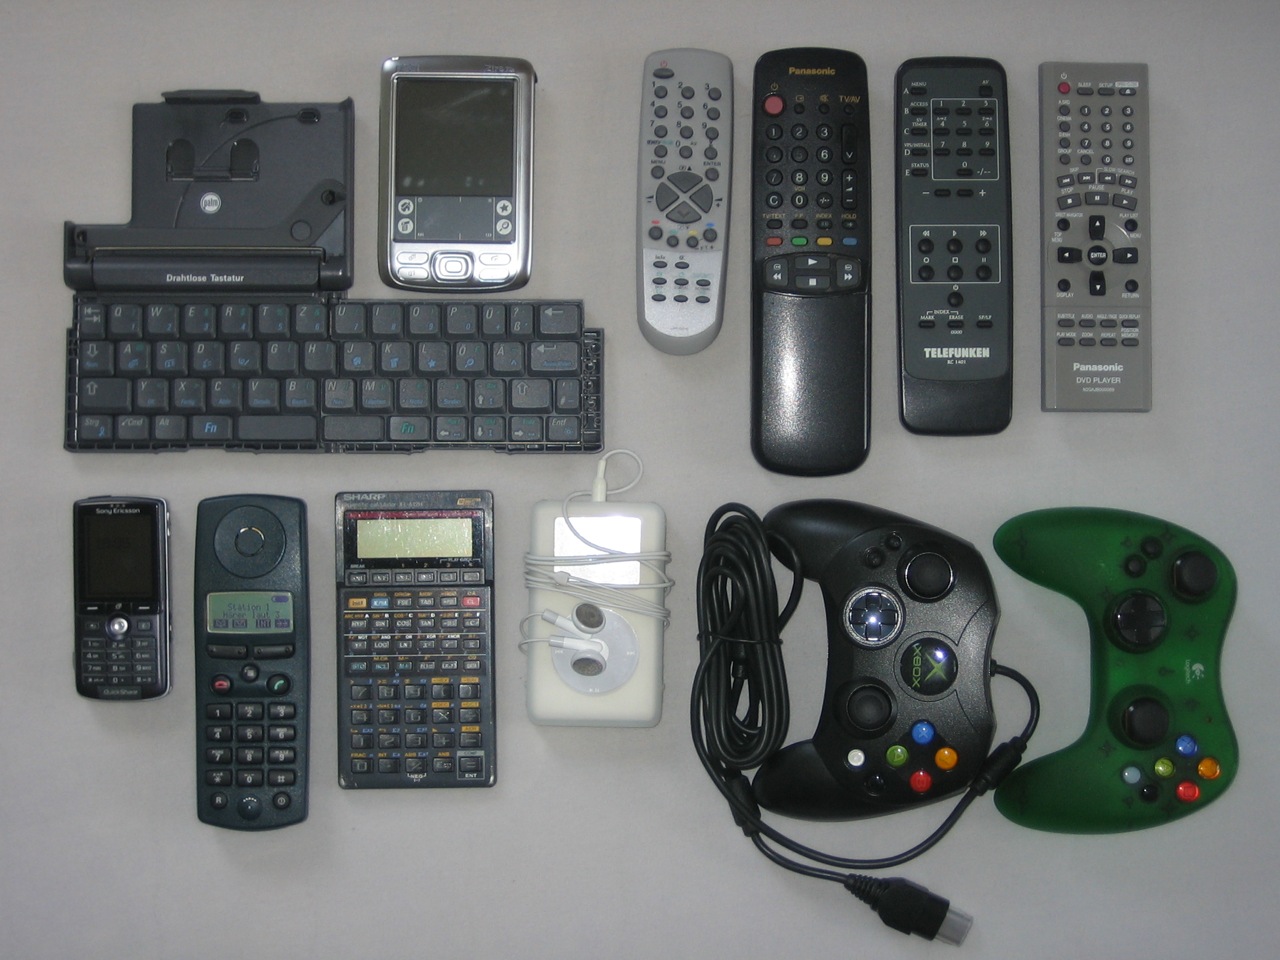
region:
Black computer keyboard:
[63, 290, 595, 458]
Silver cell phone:
[376, 50, 535, 289]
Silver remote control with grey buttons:
[636, 43, 740, 350]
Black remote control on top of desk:
[753, 43, 871, 480]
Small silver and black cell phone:
[74, 495, 169, 708]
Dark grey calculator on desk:
[328, 476, 503, 799]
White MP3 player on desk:
[524, 476, 668, 732]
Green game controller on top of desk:
[989, 500, 1246, 841]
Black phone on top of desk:
[191, 491, 315, 836]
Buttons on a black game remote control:
[878, 717, 960, 799]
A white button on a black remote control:
[845, 746, 868, 767]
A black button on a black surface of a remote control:
[862, 766, 887, 789]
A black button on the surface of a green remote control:
[1136, 781, 1157, 802]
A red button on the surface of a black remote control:
[906, 768, 931, 791]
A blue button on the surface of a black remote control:
[911, 718, 934, 743]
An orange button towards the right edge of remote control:
[935, 750, 956, 773]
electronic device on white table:
[636, 38, 723, 334]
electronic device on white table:
[749, 43, 864, 485]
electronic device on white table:
[888, 54, 1012, 438]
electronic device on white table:
[1033, 43, 1144, 419]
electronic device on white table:
[69, 491, 162, 703]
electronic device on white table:
[188, 486, 310, 827]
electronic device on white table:
[336, 484, 489, 789]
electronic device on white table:
[522, 504, 662, 734]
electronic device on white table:
[987, 505, 1237, 839]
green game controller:
[991, 483, 1243, 830]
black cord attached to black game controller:
[690, 451, 1042, 944]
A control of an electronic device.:
[326, 482, 497, 792]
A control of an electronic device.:
[889, 51, 1015, 425]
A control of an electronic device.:
[745, 45, 873, 482]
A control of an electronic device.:
[626, 49, 722, 354]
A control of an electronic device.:
[191, 497, 313, 829]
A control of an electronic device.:
[388, 49, 526, 283]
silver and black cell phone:
[378, 47, 559, 297]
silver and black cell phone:
[61, 484, 190, 719]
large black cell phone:
[204, 475, 321, 851]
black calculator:
[310, 478, 512, 803]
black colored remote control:
[762, 36, 888, 502]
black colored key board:
[41, 288, 633, 470]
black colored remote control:
[903, 41, 1029, 463]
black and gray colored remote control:
[1043, 52, 1169, 430]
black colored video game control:
[680, 493, 1025, 922]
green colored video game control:
[1009, 482, 1243, 864]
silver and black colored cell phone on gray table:
[371, 37, 535, 287]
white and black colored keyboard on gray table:
[44, 284, 612, 474]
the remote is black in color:
[748, 42, 874, 479]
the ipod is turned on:
[534, 496, 662, 720]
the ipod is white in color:
[531, 501, 666, 733]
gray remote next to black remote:
[1036, 61, 1154, 417]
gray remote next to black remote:
[634, 49, 740, 356]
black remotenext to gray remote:
[896, 55, 1020, 442]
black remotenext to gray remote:
[749, 46, 870, 478]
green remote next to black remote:
[996, 509, 1242, 832]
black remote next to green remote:
[755, 500, 1001, 819]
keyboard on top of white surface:
[61, 293, 609, 451]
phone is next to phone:
[195, 491, 313, 835]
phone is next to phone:
[73, 500, 176, 710]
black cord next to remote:
[688, 500, 1047, 941]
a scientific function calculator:
[330, 479, 498, 799]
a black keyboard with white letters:
[59, 282, 609, 461]